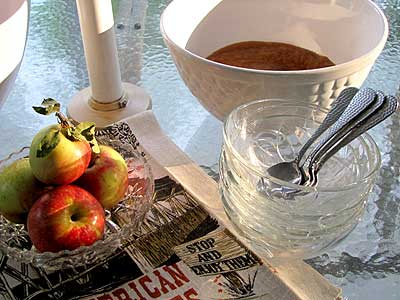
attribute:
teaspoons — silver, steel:
[254, 85, 399, 198]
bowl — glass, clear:
[221, 99, 383, 210]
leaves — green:
[31, 91, 101, 158]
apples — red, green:
[9, 97, 131, 253]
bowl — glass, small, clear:
[0, 145, 156, 270]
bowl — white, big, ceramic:
[160, 2, 390, 137]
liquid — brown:
[207, 43, 336, 72]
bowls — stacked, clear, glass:
[220, 97, 382, 265]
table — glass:
[0, 0, 398, 297]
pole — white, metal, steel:
[75, 0, 127, 111]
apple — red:
[28, 183, 106, 252]